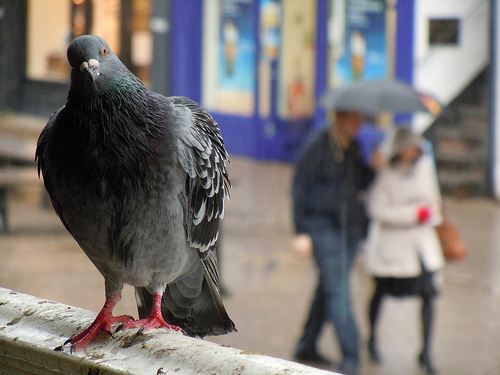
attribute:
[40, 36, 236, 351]
pigeon — forward, feathered, rightward, grey, black, gray, fluffy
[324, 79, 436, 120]
umbrella — black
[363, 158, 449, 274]
coat — white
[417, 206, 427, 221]
glove — red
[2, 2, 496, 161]
store — blue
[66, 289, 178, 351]
feet — red, pink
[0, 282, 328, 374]
railing — white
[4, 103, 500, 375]
street — wet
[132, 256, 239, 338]
tail — long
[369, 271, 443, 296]
skirt — black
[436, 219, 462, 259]
bag — brown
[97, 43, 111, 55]
eye — orange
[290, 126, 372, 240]
jacket — black